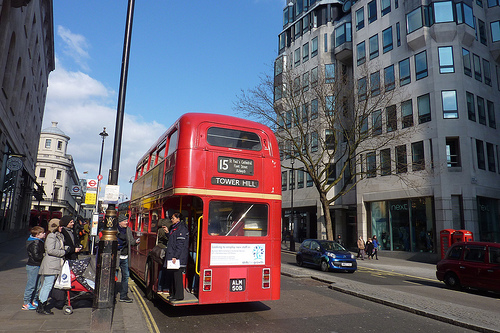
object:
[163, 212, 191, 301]
woman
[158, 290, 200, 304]
bus platform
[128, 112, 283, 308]
double decker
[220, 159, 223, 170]
number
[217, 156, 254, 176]
display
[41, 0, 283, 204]
sky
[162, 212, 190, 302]
bus operator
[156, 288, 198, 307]
stair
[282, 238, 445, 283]
sidewalk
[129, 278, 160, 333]
line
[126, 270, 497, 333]
ground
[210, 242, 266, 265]
sign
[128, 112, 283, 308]
bus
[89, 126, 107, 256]
street light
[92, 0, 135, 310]
street lamp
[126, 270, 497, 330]
street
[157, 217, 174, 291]
man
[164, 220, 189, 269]
jacket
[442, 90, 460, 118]
window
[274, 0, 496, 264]
building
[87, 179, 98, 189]
sign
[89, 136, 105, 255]
pole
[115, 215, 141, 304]
man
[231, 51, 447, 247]
tree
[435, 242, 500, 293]
car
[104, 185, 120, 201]
sign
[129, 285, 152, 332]
line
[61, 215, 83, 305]
people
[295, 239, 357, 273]
car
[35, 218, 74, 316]
woman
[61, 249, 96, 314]
stroller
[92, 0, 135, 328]
post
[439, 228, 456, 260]
telephone booth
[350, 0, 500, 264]
building